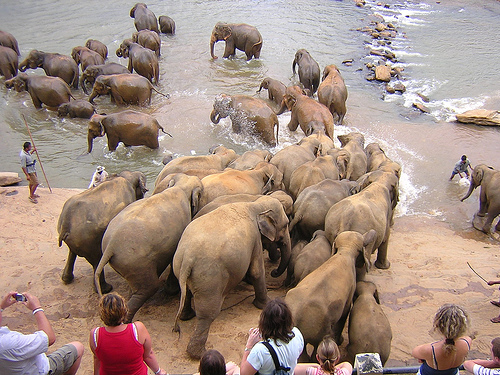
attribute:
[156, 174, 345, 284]
elephants — muddy, dirty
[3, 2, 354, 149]
elephants — brown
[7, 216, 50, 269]
sand — brown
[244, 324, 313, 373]
shirt — white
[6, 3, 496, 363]
elephant — brown 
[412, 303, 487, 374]
woman — blonde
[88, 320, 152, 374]
shirt — red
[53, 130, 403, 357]
elephants — grouped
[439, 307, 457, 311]
band — black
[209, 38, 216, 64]
trunk — elephant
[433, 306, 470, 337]
hair — frizzy